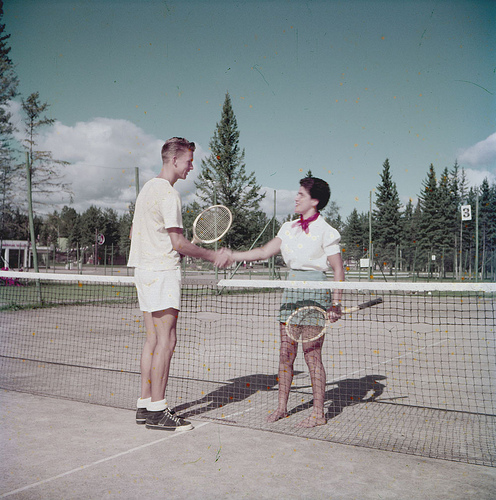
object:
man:
[126, 136, 235, 431]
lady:
[213, 175, 345, 427]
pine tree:
[344, 158, 495, 282]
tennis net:
[0, 270, 495, 467]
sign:
[461, 203, 472, 221]